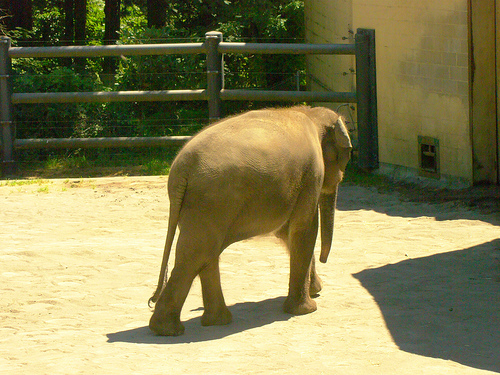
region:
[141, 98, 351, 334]
young elephant in sun on flat tan ground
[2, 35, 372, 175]
wooden fence with wire mesh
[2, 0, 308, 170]
green trees and plants behind fence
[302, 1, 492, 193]
angled corners of yellow building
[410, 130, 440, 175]
small panel with dark squares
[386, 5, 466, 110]
exposed gray bricks on wall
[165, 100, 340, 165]
fuzzy hairs on back and head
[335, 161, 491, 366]
angled and curved shadows on ground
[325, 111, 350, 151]
ear curled back on itself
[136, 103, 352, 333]
elephant standing on her shadow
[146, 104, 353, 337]
Baby elephant walking away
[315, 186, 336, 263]
Trunk of baby elephant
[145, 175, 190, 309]
Long tail of baby elephant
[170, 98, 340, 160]
Whiskers on elephant's back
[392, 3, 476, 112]
Faded paint on brick wall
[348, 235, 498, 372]
Shadow of building on the ground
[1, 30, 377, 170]
Wooden fence in background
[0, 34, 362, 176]
Wire mesh on wooden fence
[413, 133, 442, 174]
Tiny window on bottom of brick wall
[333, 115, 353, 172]
Large floppy ear of elephant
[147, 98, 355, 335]
Gray elephant walking.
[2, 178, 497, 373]
Dirt covering the ground.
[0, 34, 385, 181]
Fence in the background.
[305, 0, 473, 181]
Yellow painted bricks in the wall.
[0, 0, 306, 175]
Trees in the background.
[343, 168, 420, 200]
Green grass on the ground.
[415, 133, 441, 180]
Sign on the building.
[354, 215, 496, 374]
Shadow on the ground.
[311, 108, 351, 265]
Grey elephant trunk.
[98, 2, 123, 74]
Brown tree trunk in the background.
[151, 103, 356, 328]
the elephan is walking away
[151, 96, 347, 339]
the elephant has his back turned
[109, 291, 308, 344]
a shadow is on the ground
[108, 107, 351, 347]
the elphant is on the ground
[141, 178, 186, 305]
the elephant's tail is down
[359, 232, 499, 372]
a shadow is on the ground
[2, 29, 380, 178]
a fence is on the back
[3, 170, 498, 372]
the ground is made of dirt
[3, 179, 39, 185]
a patch of grass is on the dirt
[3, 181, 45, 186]
the grass is green in color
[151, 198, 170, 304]
Tail of zoo elephant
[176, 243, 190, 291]
Part of zoo elephant's leg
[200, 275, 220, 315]
Part of zoo elephant's leg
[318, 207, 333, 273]
Trunk of zoo elephant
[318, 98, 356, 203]
Head of zoo elephant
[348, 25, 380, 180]
Fencepost of zoo enclousure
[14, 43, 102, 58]
Rail post of zoo enclousure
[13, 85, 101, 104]
Rail post of zoo enclosoure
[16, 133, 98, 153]
rail post of zoo enclousure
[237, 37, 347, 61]
Rail post of zoo enclosoure